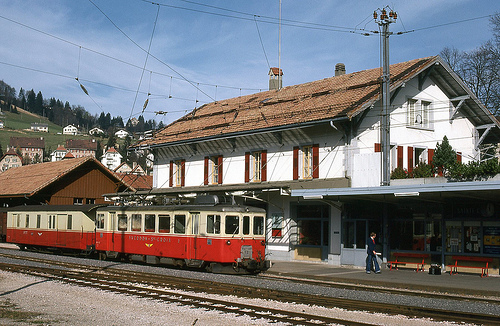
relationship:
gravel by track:
[4, 239, 480, 311] [242, 271, 496, 300]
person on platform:
[364, 229, 379, 275] [267, 258, 498, 295]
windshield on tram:
[225, 213, 238, 232] [7, 186, 270, 274]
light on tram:
[226, 236, 231, 245] [7, 186, 270, 274]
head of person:
[368, 234, 378, 242] [364, 229, 379, 275]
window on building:
[303, 147, 312, 177] [139, 56, 497, 265]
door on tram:
[190, 211, 199, 258] [7, 186, 270, 274]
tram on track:
[7, 186, 270, 274] [242, 271, 496, 300]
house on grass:
[62, 123, 81, 139] [0, 110, 93, 153]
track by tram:
[242, 271, 496, 300] [7, 186, 270, 274]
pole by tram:
[377, 26, 390, 186] [7, 186, 270, 274]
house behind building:
[62, 123, 81, 139] [139, 56, 497, 265]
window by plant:
[303, 147, 312, 177] [429, 134, 469, 181]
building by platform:
[139, 56, 497, 265] [267, 258, 498, 295]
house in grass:
[62, 123, 81, 139] [0, 110, 93, 153]